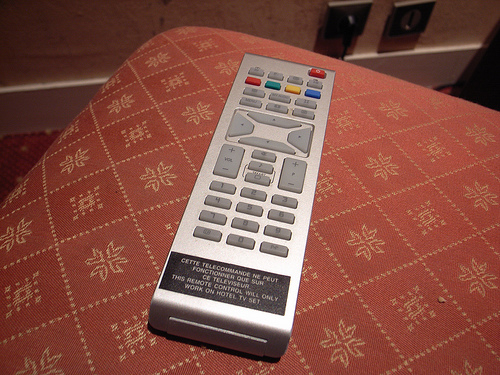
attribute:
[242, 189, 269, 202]
number — black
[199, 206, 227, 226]
number — black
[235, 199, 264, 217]
number — black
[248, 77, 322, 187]
number — black